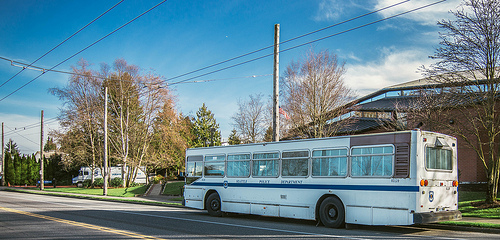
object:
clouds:
[351, 61, 407, 78]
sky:
[184, 85, 245, 99]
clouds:
[141, 21, 219, 47]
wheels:
[206, 193, 221, 216]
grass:
[472, 222, 491, 227]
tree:
[187, 102, 222, 148]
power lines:
[0, 0, 438, 137]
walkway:
[142, 181, 162, 196]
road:
[0, 186, 500, 240]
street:
[0, 188, 500, 240]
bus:
[180, 128, 461, 229]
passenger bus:
[180, 128, 460, 230]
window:
[426, 147, 452, 170]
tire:
[319, 197, 344, 229]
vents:
[393, 143, 410, 177]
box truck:
[72, 167, 146, 188]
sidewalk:
[144, 182, 164, 196]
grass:
[168, 186, 178, 191]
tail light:
[420, 179, 428, 187]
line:
[0, 204, 163, 240]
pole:
[271, 23, 280, 143]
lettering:
[236, 179, 303, 184]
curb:
[437, 221, 500, 235]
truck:
[73, 163, 148, 188]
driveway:
[0, 185, 72, 194]